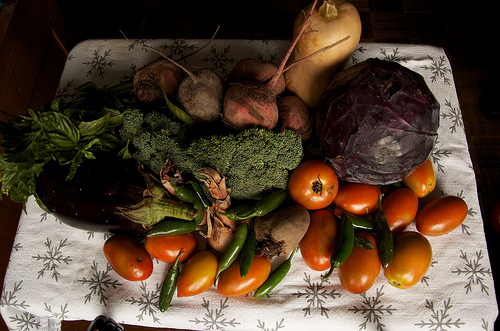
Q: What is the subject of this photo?
A: Food.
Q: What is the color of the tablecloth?
A: White.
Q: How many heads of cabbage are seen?
A: One.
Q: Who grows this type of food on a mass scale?
A: Farmer.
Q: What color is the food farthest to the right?
A: Red.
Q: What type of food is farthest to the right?
A: Tomato.